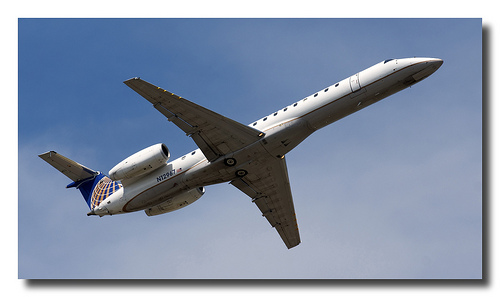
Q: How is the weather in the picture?
A: It is clear.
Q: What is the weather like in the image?
A: It is clear.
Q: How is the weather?
A: It is clear.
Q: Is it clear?
A: Yes, it is clear.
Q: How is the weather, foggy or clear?
A: It is clear.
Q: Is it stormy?
A: No, it is clear.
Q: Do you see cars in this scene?
A: No, there are no cars.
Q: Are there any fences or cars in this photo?
A: No, there are no cars or fences.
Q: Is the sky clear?
A: Yes, the sky is clear.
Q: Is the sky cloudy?
A: No, the sky is clear.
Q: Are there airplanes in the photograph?
A: Yes, there is an airplane.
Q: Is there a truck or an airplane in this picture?
A: Yes, there is an airplane.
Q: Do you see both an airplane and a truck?
A: No, there is an airplane but no trucks.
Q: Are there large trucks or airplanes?
A: Yes, there is a large airplane.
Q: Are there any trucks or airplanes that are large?
A: Yes, the airplane is large.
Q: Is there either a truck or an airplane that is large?
A: Yes, the airplane is large.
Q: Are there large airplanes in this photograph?
A: Yes, there is a large airplane.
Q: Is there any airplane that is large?
A: Yes, there is an airplane that is large.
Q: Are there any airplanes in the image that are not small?
A: Yes, there is a large airplane.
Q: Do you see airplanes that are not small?
A: Yes, there is a large airplane.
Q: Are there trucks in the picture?
A: No, there are no trucks.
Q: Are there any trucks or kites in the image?
A: No, there are no trucks or kites.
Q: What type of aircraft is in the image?
A: The aircraft is an airplane.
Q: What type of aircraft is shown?
A: The aircraft is an airplane.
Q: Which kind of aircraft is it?
A: The aircraft is an airplane.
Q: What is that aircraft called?
A: This is an airplane.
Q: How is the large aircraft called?
A: The aircraft is an airplane.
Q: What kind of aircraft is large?
A: The aircraft is an airplane.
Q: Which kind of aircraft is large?
A: The aircraft is an airplane.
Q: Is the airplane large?
A: Yes, the airplane is large.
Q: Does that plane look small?
A: No, the plane is large.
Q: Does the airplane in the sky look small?
A: No, the plane is large.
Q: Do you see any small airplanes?
A: No, there is an airplane but it is large.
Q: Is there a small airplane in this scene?
A: No, there is an airplane but it is large.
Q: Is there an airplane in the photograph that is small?
A: No, there is an airplane but it is large.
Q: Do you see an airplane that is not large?
A: No, there is an airplane but it is large.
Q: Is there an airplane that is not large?
A: No, there is an airplane but it is large.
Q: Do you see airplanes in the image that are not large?
A: No, there is an airplane but it is large.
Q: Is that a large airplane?
A: Yes, that is a large airplane.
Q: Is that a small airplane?
A: No, that is a large airplane.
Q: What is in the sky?
A: The airplane is in the sky.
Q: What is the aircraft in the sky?
A: The aircraft is an airplane.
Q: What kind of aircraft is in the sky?
A: The aircraft is an airplane.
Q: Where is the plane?
A: The plane is in the sky.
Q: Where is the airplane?
A: The plane is in the sky.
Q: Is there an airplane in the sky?
A: Yes, there is an airplane in the sky.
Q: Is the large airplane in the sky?
A: Yes, the airplane is in the sky.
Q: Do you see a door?
A: Yes, there is a door.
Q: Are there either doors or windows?
A: Yes, there is a door.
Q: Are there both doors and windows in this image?
A: Yes, there are both a door and windows.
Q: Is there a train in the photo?
A: No, there are no trains.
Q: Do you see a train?
A: No, there are no trains.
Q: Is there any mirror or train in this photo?
A: No, there are no trains or mirrors.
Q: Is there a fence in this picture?
A: No, there are no fences.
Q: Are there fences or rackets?
A: No, there are no fences or rackets.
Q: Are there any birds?
A: No, there are no birds.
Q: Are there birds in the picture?
A: No, there are no birds.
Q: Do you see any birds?
A: No, there are no birds.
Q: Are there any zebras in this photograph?
A: No, there are no zebras.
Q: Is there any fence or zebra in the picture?
A: No, there are no zebras or fences.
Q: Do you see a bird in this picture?
A: No, there are no birds.